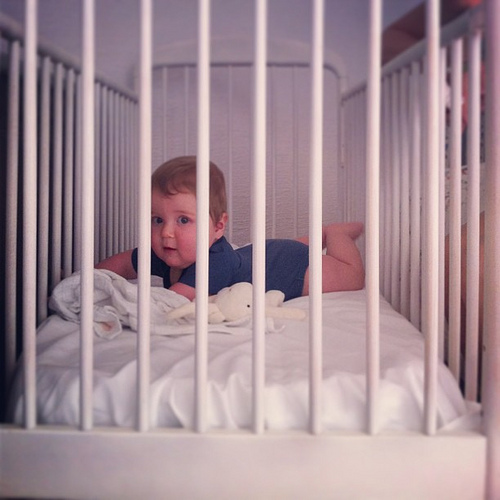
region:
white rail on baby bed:
[18, 1, 42, 428]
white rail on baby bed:
[363, 26, 385, 436]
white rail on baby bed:
[306, 0, 329, 430]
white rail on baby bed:
[424, 1, 445, 430]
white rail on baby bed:
[251, 0, 272, 427]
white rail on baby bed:
[188, 0, 212, 427]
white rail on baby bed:
[131, 1, 158, 429]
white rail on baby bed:
[4, 45, 22, 362]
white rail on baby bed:
[36, 57, 49, 315]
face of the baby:
[129, 164, 222, 269]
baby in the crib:
[2, 83, 471, 316]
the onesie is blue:
[275, 251, 294, 270]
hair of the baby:
[146, 161, 196, 187]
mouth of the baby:
[147, 240, 177, 252]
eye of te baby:
[166, 208, 195, 228]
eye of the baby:
[152, 208, 171, 230]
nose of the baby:
[153, 230, 176, 243]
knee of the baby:
[338, 266, 365, 289]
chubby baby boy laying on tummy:
[82, 148, 383, 320]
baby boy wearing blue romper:
[84, 152, 379, 312]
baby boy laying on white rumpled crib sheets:
[9, 148, 484, 423]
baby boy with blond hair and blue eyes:
[88, 148, 382, 325]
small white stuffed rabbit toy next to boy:
[164, 279, 311, 329]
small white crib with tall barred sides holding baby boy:
[5, 1, 497, 494]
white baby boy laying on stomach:
[80, 150, 380, 322]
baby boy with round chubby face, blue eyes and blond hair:
[141, 148, 233, 273]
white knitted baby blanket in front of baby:
[44, 265, 194, 332]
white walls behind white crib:
[19, 0, 499, 300]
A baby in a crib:
[55, 146, 376, 313]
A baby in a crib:
[60, 148, 370, 320]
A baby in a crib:
[56, 150, 369, 316]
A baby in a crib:
[49, 152, 371, 317]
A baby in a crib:
[60, 150, 377, 312]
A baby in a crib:
[60, 152, 370, 314]